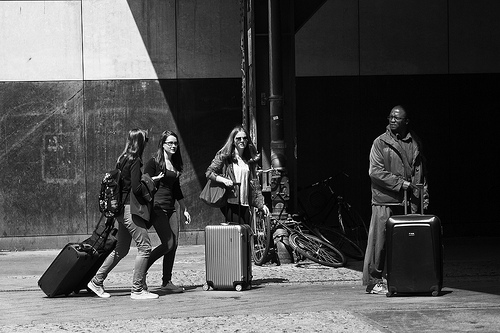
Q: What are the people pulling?
A: Suitcases.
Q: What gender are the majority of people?
A: Female.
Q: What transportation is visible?
A: Bicycle.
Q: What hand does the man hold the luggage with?
A: Right.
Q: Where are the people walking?
A: Sidewalk.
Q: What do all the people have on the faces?
A: Glasses.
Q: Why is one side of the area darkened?
A: Shadow.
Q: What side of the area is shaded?
A: Right.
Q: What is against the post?
A: Bicycles.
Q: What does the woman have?
A: Backpack.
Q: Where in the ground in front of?
A: The building.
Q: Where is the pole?
A: By the building.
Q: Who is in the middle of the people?
A: A woman.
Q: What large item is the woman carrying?
A: Luggage.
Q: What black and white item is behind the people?
A: Wall.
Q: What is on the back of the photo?
A: A black and white wall.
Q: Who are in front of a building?
A: Four people.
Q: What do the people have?
A: Three suitcases.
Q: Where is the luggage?
A: On the ground.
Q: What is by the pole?
A: Bikes.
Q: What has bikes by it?
A: Pole.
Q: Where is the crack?
A: In the wall.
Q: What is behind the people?
A: Wall.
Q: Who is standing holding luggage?
A: A man.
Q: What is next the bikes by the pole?
A: A suitcase.